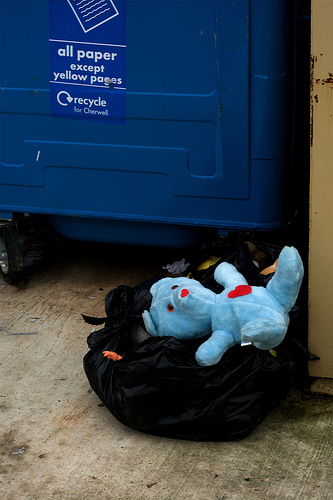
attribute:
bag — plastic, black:
[75, 239, 315, 441]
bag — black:
[122, 376, 248, 431]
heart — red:
[228, 282, 252, 299]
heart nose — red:
[180, 292, 188, 303]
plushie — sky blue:
[130, 243, 311, 373]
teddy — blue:
[142, 246, 304, 366]